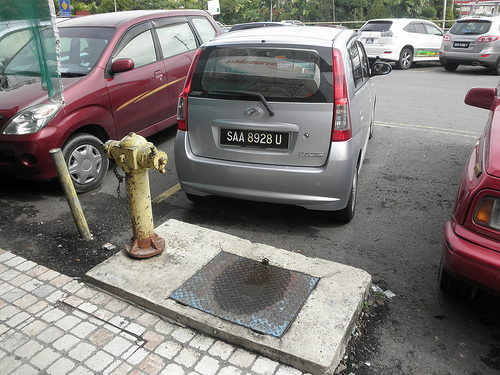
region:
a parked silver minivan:
[179, 17, 378, 217]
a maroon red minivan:
[0, 5, 218, 185]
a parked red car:
[430, 82, 499, 329]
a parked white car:
[347, 12, 446, 67]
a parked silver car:
[439, 16, 494, 74]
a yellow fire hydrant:
[97, 134, 165, 257]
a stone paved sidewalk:
[0, 247, 292, 373]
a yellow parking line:
[143, 179, 177, 204]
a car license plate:
[217, 124, 287, 150]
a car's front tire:
[57, 134, 106, 191]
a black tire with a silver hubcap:
[58, 131, 124, 199]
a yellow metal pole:
[43, 147, 96, 244]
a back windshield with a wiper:
[198, 43, 334, 114]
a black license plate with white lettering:
[214, 122, 292, 151]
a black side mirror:
[366, 55, 397, 77]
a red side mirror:
[456, 74, 498, 109]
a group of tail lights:
[173, 90, 189, 132]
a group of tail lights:
[328, 55, 353, 152]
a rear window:
[451, 15, 492, 38]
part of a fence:
[304, 15, 373, 31]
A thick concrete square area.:
[95, 203, 385, 359]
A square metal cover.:
[172, 246, 325, 334]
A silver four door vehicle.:
[165, 11, 384, 225]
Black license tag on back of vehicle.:
[214, 117, 294, 154]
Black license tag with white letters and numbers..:
[204, 119, 311, 163]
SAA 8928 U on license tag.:
[210, 117, 291, 147]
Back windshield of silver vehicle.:
[192, 35, 337, 105]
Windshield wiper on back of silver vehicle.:
[190, 37, 315, 114]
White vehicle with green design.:
[360, 8, 446, 81]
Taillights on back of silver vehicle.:
[168, 39, 368, 146]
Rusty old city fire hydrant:
[98, 120, 174, 268]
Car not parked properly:
[166, 15, 378, 226]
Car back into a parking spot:
[166, 10, 381, 232]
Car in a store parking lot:
[162, 17, 387, 232]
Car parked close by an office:
[167, 12, 392, 242]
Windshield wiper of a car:
[186, 80, 276, 120]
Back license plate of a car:
[206, 120, 298, 156]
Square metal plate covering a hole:
[161, 235, 323, 346]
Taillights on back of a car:
[321, 45, 357, 153]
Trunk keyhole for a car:
[297, 128, 314, 150]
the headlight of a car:
[9, 100, 62, 134]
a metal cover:
[166, 246, 315, 339]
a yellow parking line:
[151, 169, 178, 213]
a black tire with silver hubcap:
[398, 43, 414, 73]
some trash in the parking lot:
[365, 271, 400, 309]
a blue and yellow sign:
[55, 2, 76, 17]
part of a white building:
[448, 3, 499, 24]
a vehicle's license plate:
[364, 33, 378, 47]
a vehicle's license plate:
[451, 41, 473, 50]